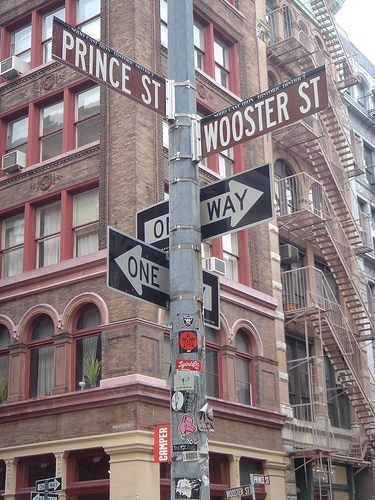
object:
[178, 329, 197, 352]
sticker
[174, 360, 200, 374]
sticker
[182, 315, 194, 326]
sticker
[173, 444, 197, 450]
sticker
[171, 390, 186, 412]
sticker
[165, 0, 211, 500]
pole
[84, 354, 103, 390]
plant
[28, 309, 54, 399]
window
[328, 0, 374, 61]
sky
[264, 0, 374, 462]
ladder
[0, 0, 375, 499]
building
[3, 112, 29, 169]
window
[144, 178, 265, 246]
arrow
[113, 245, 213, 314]
arrow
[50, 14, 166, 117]
sign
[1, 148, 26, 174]
ac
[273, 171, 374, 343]
steps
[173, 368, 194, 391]
sticker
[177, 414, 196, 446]
sticker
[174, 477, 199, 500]
sticker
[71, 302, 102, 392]
window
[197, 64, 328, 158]
sign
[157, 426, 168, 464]
word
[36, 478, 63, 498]
arrow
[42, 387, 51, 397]
plant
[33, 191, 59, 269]
window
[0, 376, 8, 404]
plant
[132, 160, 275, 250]
sign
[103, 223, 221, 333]
sign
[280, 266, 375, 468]
steps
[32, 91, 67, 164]
window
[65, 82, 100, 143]
window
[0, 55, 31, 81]
air conditioner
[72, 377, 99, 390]
window sill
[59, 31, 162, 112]
prince st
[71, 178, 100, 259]
window